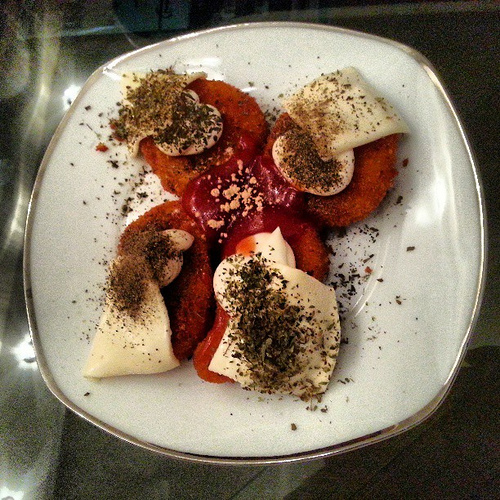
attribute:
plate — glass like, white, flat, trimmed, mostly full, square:
[23, 20, 490, 469]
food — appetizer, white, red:
[71, 43, 418, 427]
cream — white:
[235, 226, 299, 270]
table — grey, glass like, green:
[1, 1, 498, 497]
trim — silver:
[24, 20, 488, 467]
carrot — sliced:
[139, 77, 268, 198]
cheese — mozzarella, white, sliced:
[126, 70, 225, 158]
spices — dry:
[113, 66, 224, 156]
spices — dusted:
[78, 64, 402, 399]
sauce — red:
[183, 130, 305, 259]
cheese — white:
[83, 64, 411, 396]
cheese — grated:
[198, 158, 291, 244]